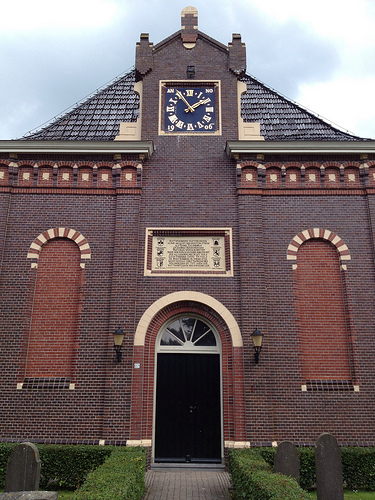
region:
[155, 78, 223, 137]
a clock in the side of a building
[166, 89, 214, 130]
the face of a clock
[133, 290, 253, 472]
an arched doorway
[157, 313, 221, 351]
a window above a door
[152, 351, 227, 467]
the door to a building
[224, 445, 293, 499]
a hedge row along a walkway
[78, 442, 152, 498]
a hedge row along a walkway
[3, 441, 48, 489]
a tombstone in a cemetary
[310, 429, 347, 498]
a tombstone in a cemetary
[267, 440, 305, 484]
a tombstone in a cemetary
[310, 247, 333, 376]
RED BRICKED WALL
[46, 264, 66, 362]
red bricked wall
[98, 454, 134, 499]
trimmed green bushes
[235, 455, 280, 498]
trimmed green bushes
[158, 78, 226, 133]
clock with blue face and roman numeral numbers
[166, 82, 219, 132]
the time on clock is 1:50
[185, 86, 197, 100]
roman numeral for the number 12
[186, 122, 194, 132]
roman numeral for the number 6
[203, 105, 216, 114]
roman numeral for the number 3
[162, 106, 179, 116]
roman numeral number 9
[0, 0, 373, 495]
a scene during the day time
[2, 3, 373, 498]
a scene of a building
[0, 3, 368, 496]
a scene outside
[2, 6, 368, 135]
a blue sky with some clouds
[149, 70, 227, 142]
a blue clock on the building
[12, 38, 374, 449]
a building made of bricks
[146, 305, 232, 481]
a black double door for the front entrance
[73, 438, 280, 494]
green hedges in the front yard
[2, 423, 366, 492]
gray tombstones in the front yard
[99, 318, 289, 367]
a couple of lights attached to the walls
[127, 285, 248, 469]
Front entrance into the building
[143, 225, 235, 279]
Large plaque in front of the building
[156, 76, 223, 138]
Clock with numbers in roman numerals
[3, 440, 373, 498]
Group of shaved bushes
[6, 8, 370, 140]
Roof of the building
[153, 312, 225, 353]
Window shaped like a semi-circle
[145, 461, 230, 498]
Sidewalk leading to the front door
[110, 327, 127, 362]
Small night light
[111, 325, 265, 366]
Couple of night lights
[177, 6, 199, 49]
Building piece with a cross logo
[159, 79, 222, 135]
square clock showing the time of 1:55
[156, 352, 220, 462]
black double doors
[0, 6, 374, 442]
red brick church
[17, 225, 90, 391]
window with rounded top that is bricked over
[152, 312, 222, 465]
rounded window over the double doors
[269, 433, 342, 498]
two old gray tombstones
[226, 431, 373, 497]
shrubs beside and behind two tombstones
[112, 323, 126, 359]
light on a brick wall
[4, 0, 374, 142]
white clouds in a blue sky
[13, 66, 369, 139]
gray shingled roof